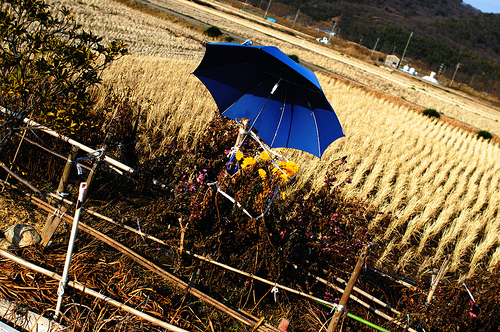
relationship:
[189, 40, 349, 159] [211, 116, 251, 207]
spokes tied to a pole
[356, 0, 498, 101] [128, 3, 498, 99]
mountain in background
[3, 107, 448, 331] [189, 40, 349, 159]
fence surrounds spokes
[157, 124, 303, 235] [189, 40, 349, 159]
flowers under spokes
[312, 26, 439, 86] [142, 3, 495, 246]
buildings on other side of field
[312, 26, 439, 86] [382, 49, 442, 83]
buildings in a cluster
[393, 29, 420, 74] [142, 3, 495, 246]
electrical pole behind field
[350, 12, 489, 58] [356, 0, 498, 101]
trees on a hill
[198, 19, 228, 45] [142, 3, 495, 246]
bush between two fields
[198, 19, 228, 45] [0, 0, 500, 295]
bush between two field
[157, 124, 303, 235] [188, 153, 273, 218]
flowers in a bunch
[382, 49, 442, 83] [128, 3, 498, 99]
farm buildings in distance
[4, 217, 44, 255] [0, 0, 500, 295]
rock on field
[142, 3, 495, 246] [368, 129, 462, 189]
field of crops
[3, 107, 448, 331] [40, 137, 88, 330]
fence has posts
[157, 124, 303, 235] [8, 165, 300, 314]
flowers in dry grass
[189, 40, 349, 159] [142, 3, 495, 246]
spokes in field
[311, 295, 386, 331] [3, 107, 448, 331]
pole on fence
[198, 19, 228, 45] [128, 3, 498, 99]
bush in distance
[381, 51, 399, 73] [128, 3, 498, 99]
barn in distance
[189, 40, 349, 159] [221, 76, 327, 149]
spokes has spokes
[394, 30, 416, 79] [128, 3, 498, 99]
electrical pole in background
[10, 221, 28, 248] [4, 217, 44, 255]
shadow on a stone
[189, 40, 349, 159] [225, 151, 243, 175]
spokes has a handle